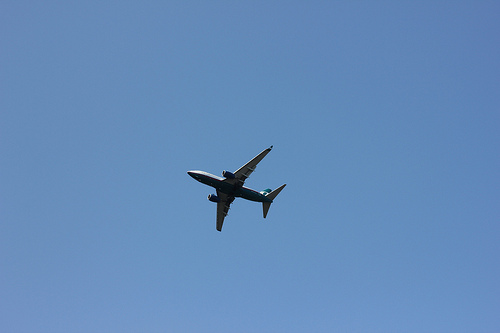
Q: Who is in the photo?
A: Nobody.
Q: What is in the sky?
A: An airplane.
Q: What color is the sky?
A: Blue.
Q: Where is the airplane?
A: In the sky.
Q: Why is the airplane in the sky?
A: It is flying.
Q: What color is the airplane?
A: Gray.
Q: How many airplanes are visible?
A: One.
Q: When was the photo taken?
A: Daytime.